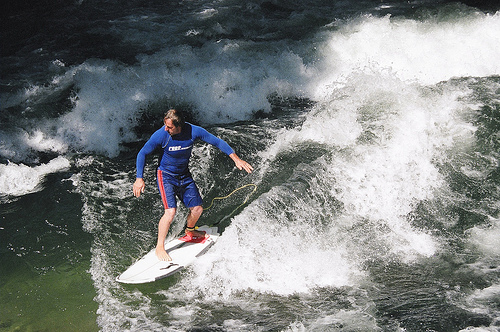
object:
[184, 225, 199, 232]
band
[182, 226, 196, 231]
ankle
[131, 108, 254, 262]
man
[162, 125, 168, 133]
nose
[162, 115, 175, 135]
face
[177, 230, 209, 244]
red logo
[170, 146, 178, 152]
writing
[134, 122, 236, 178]
shirt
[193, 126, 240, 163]
arm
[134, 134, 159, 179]
arm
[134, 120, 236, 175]
wetsuit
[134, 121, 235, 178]
blue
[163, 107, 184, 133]
hair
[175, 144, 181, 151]
writing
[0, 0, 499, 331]
water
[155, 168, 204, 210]
blue shorts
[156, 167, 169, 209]
red stripe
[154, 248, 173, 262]
foot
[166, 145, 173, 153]
white lettering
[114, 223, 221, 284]
surfboard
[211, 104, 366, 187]
wall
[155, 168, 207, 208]
wetsuit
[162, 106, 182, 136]
head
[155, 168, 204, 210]
blue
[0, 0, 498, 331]
riding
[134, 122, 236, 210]
wearing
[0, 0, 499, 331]
splashing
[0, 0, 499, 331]
forward